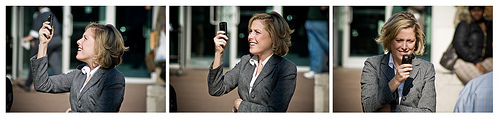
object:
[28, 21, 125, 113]
woman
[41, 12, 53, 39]
phone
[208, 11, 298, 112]
woman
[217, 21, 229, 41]
phone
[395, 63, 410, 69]
finger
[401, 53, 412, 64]
phone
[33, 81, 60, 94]
elbow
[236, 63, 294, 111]
arm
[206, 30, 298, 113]
body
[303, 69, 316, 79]
shoe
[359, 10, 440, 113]
woman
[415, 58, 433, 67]
shoulder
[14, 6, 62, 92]
person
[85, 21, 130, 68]
hair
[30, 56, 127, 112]
suit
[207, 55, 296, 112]
suit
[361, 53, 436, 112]
suit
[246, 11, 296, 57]
hair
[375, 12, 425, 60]
hair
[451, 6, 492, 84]
person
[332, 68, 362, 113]
sidewalk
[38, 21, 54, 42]
hand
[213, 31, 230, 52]
hand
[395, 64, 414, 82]
hand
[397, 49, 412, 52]
smile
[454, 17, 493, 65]
jacket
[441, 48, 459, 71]
bag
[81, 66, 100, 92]
shirt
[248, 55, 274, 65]
collar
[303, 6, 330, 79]
person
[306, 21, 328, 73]
jeans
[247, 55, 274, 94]
shirt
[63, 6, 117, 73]
door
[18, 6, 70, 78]
door